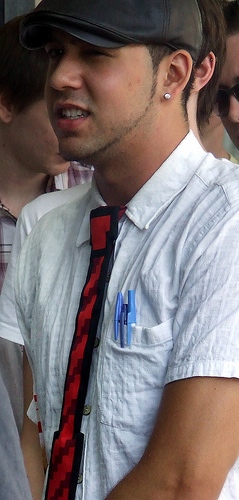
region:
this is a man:
[55, 28, 235, 370]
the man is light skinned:
[167, 416, 221, 470]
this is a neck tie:
[69, 306, 100, 373]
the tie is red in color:
[63, 369, 82, 390]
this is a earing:
[165, 93, 176, 97]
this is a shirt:
[149, 233, 218, 297]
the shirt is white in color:
[155, 275, 213, 327]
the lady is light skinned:
[5, 174, 30, 196]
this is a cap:
[123, 11, 170, 33]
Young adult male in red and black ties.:
[1, 0, 237, 499]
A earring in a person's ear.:
[162, 93, 171, 100]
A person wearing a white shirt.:
[14, 0, 238, 499]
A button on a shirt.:
[81, 404, 91, 415]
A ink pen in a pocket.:
[126, 288, 137, 349]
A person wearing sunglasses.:
[216, 0, 238, 150]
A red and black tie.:
[43, 205, 128, 499]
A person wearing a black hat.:
[20, 0, 238, 498]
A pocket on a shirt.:
[96, 312, 173, 435]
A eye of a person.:
[44, 43, 64, 62]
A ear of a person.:
[157, 47, 192, 103]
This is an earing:
[163, 73, 189, 117]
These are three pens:
[91, 293, 192, 428]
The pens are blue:
[110, 291, 178, 440]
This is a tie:
[55, 346, 112, 445]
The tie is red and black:
[72, 345, 78, 487]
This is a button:
[74, 399, 96, 415]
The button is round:
[83, 389, 103, 465]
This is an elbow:
[131, 413, 230, 498]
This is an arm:
[21, 426, 53, 482]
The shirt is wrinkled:
[135, 401, 144, 444]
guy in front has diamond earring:
[163, 92, 170, 99]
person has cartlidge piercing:
[210, 56, 218, 62]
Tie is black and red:
[45, 204, 127, 498]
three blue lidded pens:
[113, 291, 136, 346]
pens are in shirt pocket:
[98, 289, 175, 433]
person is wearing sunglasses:
[211, 82, 238, 117]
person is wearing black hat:
[18, 0, 202, 63]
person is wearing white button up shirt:
[12, 131, 235, 498]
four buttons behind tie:
[74, 272, 111, 483]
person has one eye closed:
[43, 40, 116, 60]